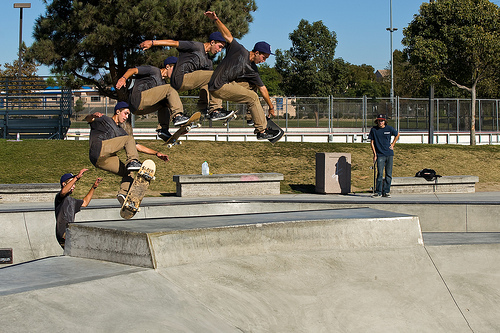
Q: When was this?
A: Daytime.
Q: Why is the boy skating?
A: For fun.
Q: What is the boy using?
A: Skateboard.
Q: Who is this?
A: A boy.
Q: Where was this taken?
A: At a skatepark.